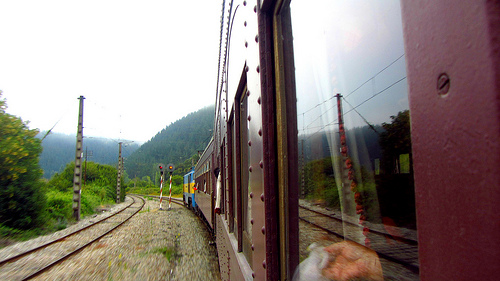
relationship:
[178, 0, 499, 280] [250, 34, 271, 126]
train has rivets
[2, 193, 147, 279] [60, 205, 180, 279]
track have gravel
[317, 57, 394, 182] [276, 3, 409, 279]
reflection in glass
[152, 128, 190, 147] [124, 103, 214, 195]
trees cover hills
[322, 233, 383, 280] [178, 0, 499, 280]
hand inside train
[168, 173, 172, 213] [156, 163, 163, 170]
pole have light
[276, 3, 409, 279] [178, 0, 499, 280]
window on train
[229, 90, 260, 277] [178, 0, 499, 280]
window on train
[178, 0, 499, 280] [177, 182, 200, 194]
train with stripe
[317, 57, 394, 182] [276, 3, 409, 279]
reflection in window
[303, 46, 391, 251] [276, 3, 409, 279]
curtain in window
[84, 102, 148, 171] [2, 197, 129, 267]
power lines beside track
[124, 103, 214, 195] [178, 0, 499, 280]
mountain behind train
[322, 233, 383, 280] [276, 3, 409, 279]
hand through window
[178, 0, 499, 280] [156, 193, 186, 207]
train on tracks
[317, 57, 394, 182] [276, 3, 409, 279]
reflection on window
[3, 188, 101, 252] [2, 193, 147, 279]
grass along track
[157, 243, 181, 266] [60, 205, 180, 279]
grass in gravel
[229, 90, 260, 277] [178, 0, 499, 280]
window of train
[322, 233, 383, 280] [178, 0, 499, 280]
hand in train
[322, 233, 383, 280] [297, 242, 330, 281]
hand holding item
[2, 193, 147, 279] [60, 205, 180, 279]
track and gravel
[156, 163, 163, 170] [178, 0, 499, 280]
light of train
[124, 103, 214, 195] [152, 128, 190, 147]
hill with trees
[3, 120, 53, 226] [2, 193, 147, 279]
bushes beside track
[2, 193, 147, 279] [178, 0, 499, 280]
track of train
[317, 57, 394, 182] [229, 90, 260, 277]
reflection on window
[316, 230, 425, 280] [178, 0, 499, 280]
passenger riding train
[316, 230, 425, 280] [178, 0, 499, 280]
passenger on train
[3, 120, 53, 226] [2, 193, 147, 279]
bushes along track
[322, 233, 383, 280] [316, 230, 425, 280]
hand of passenger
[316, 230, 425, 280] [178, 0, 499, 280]
passenger of train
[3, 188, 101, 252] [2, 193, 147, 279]
grass near track